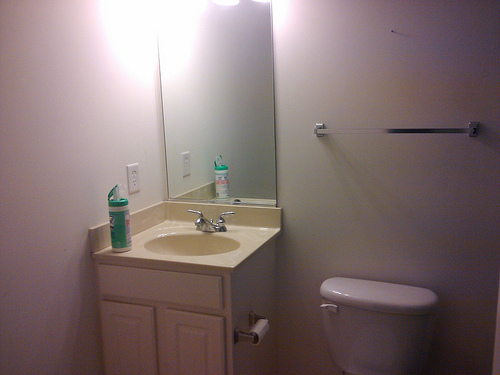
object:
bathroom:
[0, 0, 499, 374]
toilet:
[318, 276, 441, 375]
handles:
[187, 209, 206, 217]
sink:
[144, 233, 242, 255]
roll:
[250, 318, 270, 346]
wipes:
[105, 184, 133, 253]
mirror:
[154, 1, 277, 207]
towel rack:
[313, 123, 480, 139]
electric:
[126, 161, 141, 195]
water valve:
[186, 209, 235, 234]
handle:
[319, 303, 338, 314]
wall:
[272, 0, 500, 375]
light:
[83, 0, 197, 112]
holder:
[229, 315, 236, 333]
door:
[97, 297, 161, 375]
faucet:
[195, 218, 205, 227]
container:
[108, 198, 134, 253]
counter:
[93, 218, 281, 266]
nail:
[391, 30, 395, 32]